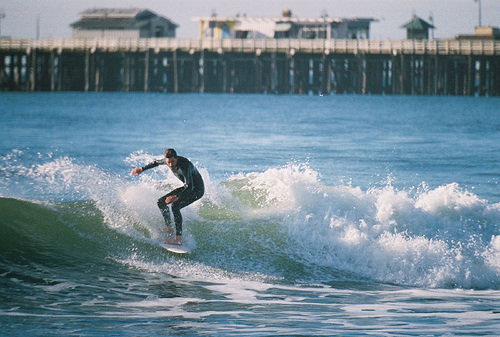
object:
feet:
[161, 237, 182, 245]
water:
[0, 92, 500, 337]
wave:
[0, 146, 500, 337]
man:
[128, 147, 205, 245]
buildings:
[66, 4, 178, 41]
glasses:
[163, 152, 179, 159]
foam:
[0, 254, 500, 337]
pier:
[0, 38, 500, 100]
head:
[163, 147, 179, 169]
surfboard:
[153, 236, 189, 254]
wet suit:
[142, 154, 205, 236]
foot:
[153, 226, 175, 233]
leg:
[170, 186, 206, 239]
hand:
[129, 167, 143, 176]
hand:
[163, 194, 179, 205]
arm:
[140, 157, 166, 172]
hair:
[163, 147, 177, 160]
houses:
[66, 6, 181, 41]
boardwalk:
[0, 37, 500, 99]